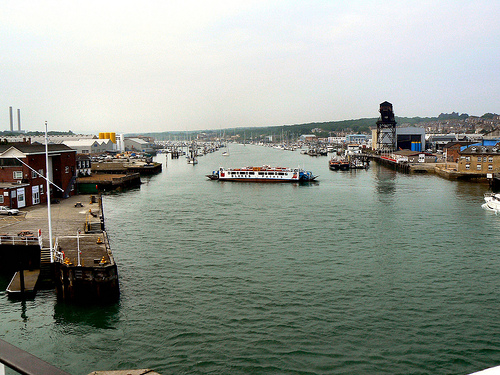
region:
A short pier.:
[48, 226, 141, 318]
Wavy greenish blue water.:
[181, 191, 456, 336]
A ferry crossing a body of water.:
[197, 161, 327, 192]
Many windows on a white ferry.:
[215, 163, 301, 188]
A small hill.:
[407, 105, 495, 140]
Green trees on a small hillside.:
[248, 118, 390, 134]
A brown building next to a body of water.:
[449, 134, 498, 182]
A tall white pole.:
[31, 112, 70, 269]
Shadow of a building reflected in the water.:
[363, 158, 413, 203]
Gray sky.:
[16, 32, 313, 121]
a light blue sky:
[258, 0, 303, 14]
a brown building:
[0, 141, 80, 210]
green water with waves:
[148, 297, 312, 351]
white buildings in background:
[61, 135, 114, 152]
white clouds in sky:
[108, 23, 181, 51]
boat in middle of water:
[203, 165, 326, 184]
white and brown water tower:
[378, 94, 398, 151]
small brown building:
[461, 142, 498, 169]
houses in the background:
[410, 114, 495, 134]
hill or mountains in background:
[258, 115, 476, 134]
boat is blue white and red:
[189, 158, 340, 192]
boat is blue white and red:
[216, 140, 291, 202]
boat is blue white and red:
[203, 154, 347, 217]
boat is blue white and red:
[203, 168, 319, 189]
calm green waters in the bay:
[189, 259, 336, 362]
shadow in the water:
[371, 164, 416, 213]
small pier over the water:
[4, 263, 66, 320]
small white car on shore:
[6, 199, 73, 226]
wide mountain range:
[208, 117, 362, 143]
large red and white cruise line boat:
[203, 147, 338, 205]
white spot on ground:
[64, 199, 105, 224]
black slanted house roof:
[5, 136, 104, 179]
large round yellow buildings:
[89, 130, 128, 147]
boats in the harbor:
[173, 126, 408, 223]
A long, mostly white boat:
[196, 156, 325, 193]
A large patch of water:
[73, 91, 499, 367]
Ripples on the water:
[200, 259, 401, 348]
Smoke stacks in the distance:
[3, 96, 30, 141]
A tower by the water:
[358, 92, 410, 192]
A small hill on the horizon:
[128, 94, 499, 166]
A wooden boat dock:
[41, 220, 137, 319]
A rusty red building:
[0, 131, 96, 216]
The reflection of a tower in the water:
[364, 157, 414, 212]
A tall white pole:
[28, 115, 81, 290]